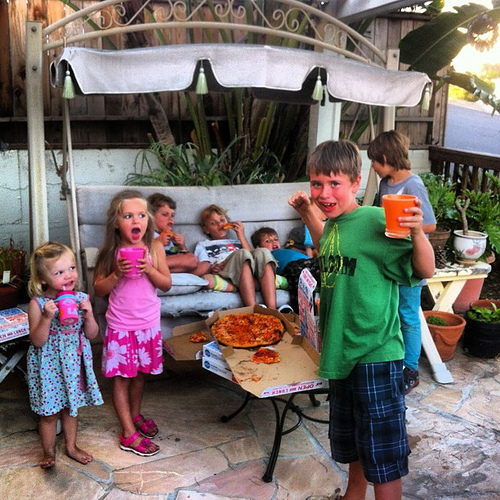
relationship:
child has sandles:
[88, 190, 174, 459] [116, 412, 161, 459]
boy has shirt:
[194, 199, 292, 318] [196, 233, 242, 265]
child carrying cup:
[25, 240, 100, 473] [48, 293, 84, 323]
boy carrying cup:
[287, 140, 434, 499] [379, 185, 419, 240]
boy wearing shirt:
[279, 137, 444, 498] [300, 205, 407, 362]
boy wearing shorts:
[279, 137, 444, 498] [322, 357, 414, 484]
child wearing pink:
[25, 240, 99, 469] [106, 271, 162, 375]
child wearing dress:
[25, 240, 99, 469] [30, 290, 100, 415]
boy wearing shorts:
[287, 140, 434, 499] [322, 357, 414, 484]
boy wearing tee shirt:
[287, 140, 434, 499] [308, 203, 417, 382]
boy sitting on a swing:
[249, 221, 324, 341] [28, 17, 443, 354]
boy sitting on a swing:
[194, 204, 278, 311] [28, 17, 443, 354]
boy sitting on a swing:
[140, 190, 210, 285] [28, 17, 443, 354]